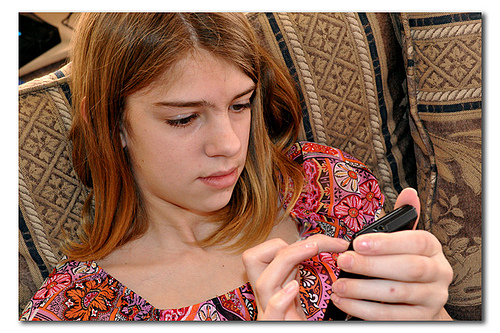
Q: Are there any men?
A: No, there are no men.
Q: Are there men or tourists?
A: No, there are no men or tourists.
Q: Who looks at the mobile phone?
A: The girl looks at the mobile phone.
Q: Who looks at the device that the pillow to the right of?
A: The girl looks at the mobile phone.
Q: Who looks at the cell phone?
A: The girl looks at the mobile phone.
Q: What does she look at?
A: The girl looks at the cell phone.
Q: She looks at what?
A: The girl looks at the cell phone.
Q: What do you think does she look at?
A: The girl looks at the cell phone.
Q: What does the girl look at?
A: The girl looks at the cell phone.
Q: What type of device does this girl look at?
A: The girl looks at the mobile phone.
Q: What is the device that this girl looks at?
A: The device is a cell phone.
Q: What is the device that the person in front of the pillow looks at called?
A: The device is a cell phone.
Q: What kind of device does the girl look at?
A: The girl looks at the mobile phone.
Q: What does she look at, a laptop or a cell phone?
A: The girl looks at a cell phone.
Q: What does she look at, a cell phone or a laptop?
A: The girl looks at a cell phone.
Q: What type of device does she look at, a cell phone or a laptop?
A: The girl looks at a cell phone.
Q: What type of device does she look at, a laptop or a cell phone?
A: The girl looks at a cell phone.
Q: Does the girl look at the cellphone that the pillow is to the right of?
A: Yes, the girl looks at the cell phone.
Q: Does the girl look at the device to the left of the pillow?
A: Yes, the girl looks at the cell phone.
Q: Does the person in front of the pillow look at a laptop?
A: No, the girl looks at the cell phone.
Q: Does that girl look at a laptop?
A: No, the girl looks at the cell phone.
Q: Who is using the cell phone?
A: The girl is using the cell phone.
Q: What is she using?
A: The girl is using a mobile phone.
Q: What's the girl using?
A: The girl is using a mobile phone.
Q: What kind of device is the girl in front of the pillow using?
A: The girl is using a mobile phone.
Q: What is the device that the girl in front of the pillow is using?
A: The device is a cell phone.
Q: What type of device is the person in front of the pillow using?
A: The girl is using a mobile phone.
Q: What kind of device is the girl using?
A: The girl is using a mobile phone.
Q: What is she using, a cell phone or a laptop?
A: The girl is using a cell phone.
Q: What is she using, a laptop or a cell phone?
A: The girl is using a cell phone.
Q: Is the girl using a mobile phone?
A: Yes, the girl is using a mobile phone.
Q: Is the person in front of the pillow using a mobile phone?
A: Yes, the girl is using a mobile phone.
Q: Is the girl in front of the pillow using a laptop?
A: No, the girl is using a mobile phone.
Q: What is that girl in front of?
A: The girl is in front of the pillow.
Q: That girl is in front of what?
A: The girl is in front of the pillow.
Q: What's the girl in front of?
A: The girl is in front of the pillow.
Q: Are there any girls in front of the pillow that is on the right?
A: Yes, there is a girl in front of the pillow.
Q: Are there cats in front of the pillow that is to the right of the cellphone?
A: No, there is a girl in front of the pillow.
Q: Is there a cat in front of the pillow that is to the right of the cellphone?
A: No, there is a girl in front of the pillow.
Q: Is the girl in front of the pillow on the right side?
A: Yes, the girl is in front of the pillow.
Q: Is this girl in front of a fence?
A: No, the girl is in front of the pillow.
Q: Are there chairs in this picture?
A: No, there are no chairs.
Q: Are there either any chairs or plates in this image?
A: No, there are no chairs or plates.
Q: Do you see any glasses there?
A: No, there are no glasses.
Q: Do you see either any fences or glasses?
A: No, there are no glasses or fences.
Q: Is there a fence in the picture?
A: No, there are no fences.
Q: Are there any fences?
A: No, there are no fences.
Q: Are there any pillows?
A: Yes, there is a pillow.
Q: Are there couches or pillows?
A: Yes, there is a pillow.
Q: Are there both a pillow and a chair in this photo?
A: No, there is a pillow but no chairs.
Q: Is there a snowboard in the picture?
A: No, there are no snowboards.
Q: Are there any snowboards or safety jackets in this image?
A: No, there are no snowboards or safety jackets.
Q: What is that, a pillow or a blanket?
A: That is a pillow.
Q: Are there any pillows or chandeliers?
A: Yes, there is a pillow.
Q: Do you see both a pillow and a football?
A: No, there is a pillow but no footballs.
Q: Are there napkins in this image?
A: No, there are no napkins.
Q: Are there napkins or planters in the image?
A: No, there are no napkins or planters.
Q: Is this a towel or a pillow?
A: This is a pillow.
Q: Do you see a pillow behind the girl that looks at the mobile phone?
A: Yes, there is a pillow behind the girl.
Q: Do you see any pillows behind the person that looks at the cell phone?
A: Yes, there is a pillow behind the girl.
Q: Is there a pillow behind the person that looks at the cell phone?
A: Yes, there is a pillow behind the girl.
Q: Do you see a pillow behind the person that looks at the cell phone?
A: Yes, there is a pillow behind the girl.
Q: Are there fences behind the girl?
A: No, there is a pillow behind the girl.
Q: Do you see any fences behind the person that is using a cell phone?
A: No, there is a pillow behind the girl.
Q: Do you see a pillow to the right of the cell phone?
A: Yes, there is a pillow to the right of the cell phone.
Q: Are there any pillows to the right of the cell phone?
A: Yes, there is a pillow to the right of the cell phone.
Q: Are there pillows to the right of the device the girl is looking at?
A: Yes, there is a pillow to the right of the cell phone.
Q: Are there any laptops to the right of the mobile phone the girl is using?
A: No, there is a pillow to the right of the cell phone.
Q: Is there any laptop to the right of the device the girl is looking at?
A: No, there is a pillow to the right of the cell phone.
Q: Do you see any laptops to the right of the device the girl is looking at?
A: No, there is a pillow to the right of the cell phone.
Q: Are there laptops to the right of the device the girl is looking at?
A: No, there is a pillow to the right of the cell phone.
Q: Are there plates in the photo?
A: No, there are no plates.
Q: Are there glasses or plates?
A: No, there are no plates or glasses.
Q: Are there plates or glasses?
A: No, there are no plates or glasses.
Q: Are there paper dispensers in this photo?
A: No, there are no paper dispensers.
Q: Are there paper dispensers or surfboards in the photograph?
A: No, there are no paper dispensers or surfboards.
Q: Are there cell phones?
A: Yes, there is a cell phone.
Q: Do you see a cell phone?
A: Yes, there is a cell phone.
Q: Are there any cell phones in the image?
A: Yes, there is a cell phone.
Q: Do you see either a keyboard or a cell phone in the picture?
A: Yes, there is a cell phone.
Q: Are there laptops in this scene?
A: No, there are no laptops.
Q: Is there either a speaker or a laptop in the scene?
A: No, there are no laptops or speakers.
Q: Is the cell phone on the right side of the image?
A: Yes, the cell phone is on the right of the image.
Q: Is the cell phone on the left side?
A: No, the cell phone is on the right of the image.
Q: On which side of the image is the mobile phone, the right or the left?
A: The mobile phone is on the right of the image.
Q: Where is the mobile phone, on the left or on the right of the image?
A: The mobile phone is on the right of the image.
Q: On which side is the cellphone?
A: The cellphone is on the right of the image.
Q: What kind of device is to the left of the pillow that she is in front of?
A: The device is a cell phone.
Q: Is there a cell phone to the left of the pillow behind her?
A: Yes, there is a cell phone to the left of the pillow.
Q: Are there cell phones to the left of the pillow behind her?
A: Yes, there is a cell phone to the left of the pillow.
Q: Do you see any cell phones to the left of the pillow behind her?
A: Yes, there is a cell phone to the left of the pillow.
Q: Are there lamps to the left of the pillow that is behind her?
A: No, there is a cell phone to the left of the pillow.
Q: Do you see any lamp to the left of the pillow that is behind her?
A: No, there is a cell phone to the left of the pillow.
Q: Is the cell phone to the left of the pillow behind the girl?
A: Yes, the cell phone is to the left of the pillow.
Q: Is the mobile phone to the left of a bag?
A: No, the mobile phone is to the left of the pillow.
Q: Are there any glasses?
A: No, there are no glasses.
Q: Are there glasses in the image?
A: No, there are no glasses.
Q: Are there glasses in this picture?
A: No, there are no glasses.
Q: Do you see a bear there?
A: No, there are no bears.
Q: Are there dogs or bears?
A: No, there are no bears or dogs.